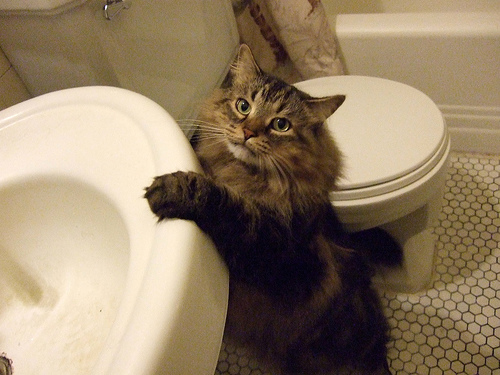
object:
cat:
[140, 42, 404, 373]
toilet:
[1, 0, 450, 294]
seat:
[287, 74, 448, 203]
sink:
[1, 84, 230, 375]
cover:
[286, 73, 446, 191]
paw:
[140, 166, 222, 227]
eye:
[233, 96, 254, 118]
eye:
[270, 116, 293, 134]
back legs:
[279, 340, 393, 375]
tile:
[443, 151, 500, 253]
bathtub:
[328, 0, 499, 155]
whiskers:
[256, 150, 303, 196]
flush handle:
[103, 0, 124, 21]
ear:
[230, 42, 263, 86]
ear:
[309, 91, 347, 125]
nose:
[241, 125, 258, 140]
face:
[224, 89, 298, 164]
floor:
[442, 125, 500, 374]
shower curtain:
[233, 0, 349, 85]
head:
[197, 42, 345, 170]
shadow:
[383, 308, 487, 375]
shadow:
[1, 253, 45, 308]